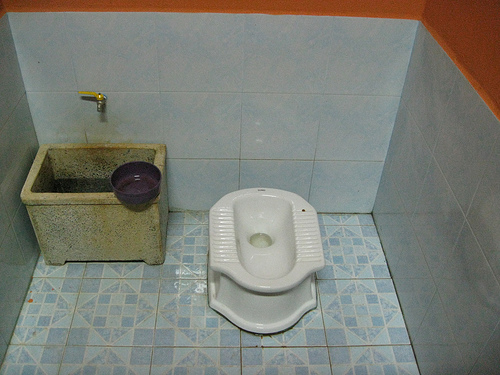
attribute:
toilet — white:
[208, 175, 330, 333]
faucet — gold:
[71, 87, 127, 119]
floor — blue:
[67, 280, 173, 374]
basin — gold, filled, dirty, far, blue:
[35, 141, 176, 264]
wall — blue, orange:
[228, 38, 285, 92]